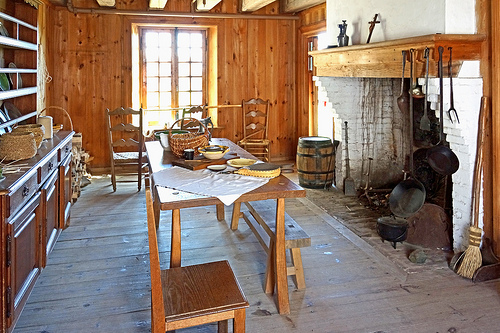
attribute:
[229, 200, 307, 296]
bench — brown, wooden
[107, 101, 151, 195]
chair — brown, wooden, empty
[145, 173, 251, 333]
chair — brown, empty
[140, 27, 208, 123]
window — large, sunny, bright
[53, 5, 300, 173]
wall — wooden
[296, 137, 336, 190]
barrel — wooden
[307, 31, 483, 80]
mantle — large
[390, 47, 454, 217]
cooking utensils — cast iron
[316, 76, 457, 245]
fireplace — white brick, unlit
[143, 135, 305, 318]
table — large, wooden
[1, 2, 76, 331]
china cabinet — large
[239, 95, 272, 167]
chair — empty, brown, wood